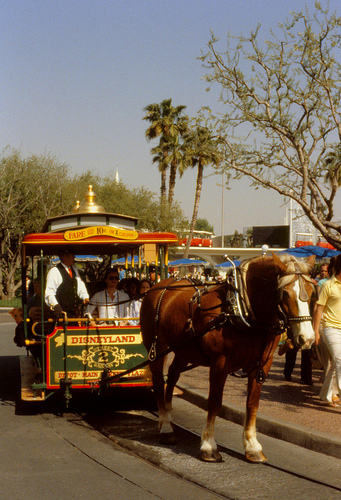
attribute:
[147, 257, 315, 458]
horse — brown and white, brown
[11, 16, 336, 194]
clouds — white 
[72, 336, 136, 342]
letters — red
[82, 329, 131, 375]
number 2 — written , on the front 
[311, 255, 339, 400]
woman — wearing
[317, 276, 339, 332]
shirt — yellow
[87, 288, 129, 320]
shirt — white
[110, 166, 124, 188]
tower — white 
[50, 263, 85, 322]
coat — black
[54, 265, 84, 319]
vest — black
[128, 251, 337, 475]
horse — blown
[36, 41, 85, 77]
sky — blue 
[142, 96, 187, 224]
tree — tall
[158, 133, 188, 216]
tree — tall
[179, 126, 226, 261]
tree — tall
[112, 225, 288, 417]
horse — brown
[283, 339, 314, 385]
pants — black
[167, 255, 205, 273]
umbrella — blue , large 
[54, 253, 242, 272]
umbrellas — blue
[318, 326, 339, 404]
pants — white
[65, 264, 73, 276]
tie — red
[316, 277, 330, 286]
shirt — blue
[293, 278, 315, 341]
stripe — white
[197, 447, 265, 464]
hooves — white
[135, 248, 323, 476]
fur — blown